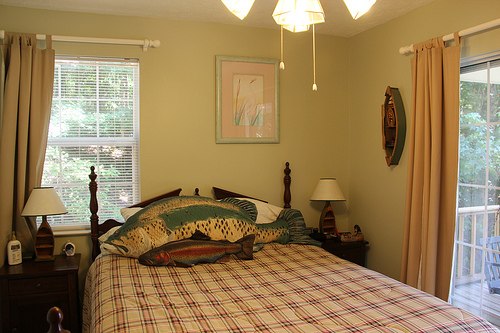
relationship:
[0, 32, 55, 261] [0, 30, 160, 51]
curtain on rod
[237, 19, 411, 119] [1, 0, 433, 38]
fixture hanging from ceiling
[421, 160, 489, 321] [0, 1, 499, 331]
balcony off bedroom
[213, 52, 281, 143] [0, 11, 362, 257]
picture on wall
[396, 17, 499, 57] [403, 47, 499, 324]
curtainrod above window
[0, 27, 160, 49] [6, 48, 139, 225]
curtainrod above window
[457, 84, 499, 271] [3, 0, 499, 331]
woods surrounding room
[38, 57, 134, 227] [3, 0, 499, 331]
woods surrounding room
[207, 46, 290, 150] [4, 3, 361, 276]
picture hanging on wall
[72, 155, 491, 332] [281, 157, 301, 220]
bed has post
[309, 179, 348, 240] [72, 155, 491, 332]
lamp by bed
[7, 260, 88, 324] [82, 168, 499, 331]
table next to bed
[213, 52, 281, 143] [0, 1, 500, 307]
picture hanging on wall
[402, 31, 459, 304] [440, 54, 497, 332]
curtains are hanging on doorway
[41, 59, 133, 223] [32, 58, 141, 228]
mini blinds on window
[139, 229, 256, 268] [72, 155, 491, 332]
fish pillow on bed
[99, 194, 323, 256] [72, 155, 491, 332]
fish pillow on bed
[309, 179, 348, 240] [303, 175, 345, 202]
lamp with shade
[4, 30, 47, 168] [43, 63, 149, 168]
curtain on window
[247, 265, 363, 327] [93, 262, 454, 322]
spread on bed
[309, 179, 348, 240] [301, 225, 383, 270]
lamp on stand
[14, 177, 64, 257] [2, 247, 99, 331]
lamp on stand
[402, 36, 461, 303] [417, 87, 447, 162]
curtains has pleats